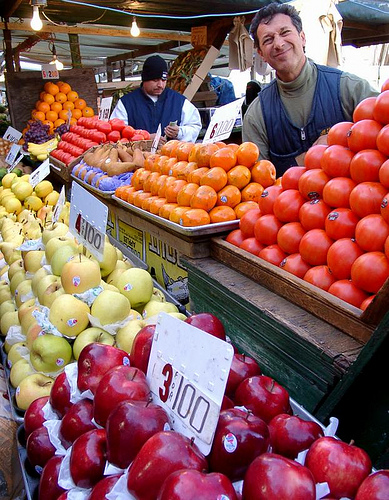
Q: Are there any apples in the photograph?
A: Yes, there are apples.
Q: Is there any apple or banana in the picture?
A: Yes, there are apples.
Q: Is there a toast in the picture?
A: No, there are no toasts.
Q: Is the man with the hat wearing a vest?
A: Yes, the man is wearing a vest.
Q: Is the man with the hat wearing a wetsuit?
A: No, the man is wearing a vest.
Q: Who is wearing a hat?
A: The man is wearing a hat.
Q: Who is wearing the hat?
A: The man is wearing a hat.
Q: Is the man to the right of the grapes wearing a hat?
A: Yes, the man is wearing a hat.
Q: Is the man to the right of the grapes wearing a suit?
A: No, the man is wearing a hat.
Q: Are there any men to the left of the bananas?
A: No, the man is to the right of the bananas.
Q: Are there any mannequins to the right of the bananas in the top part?
A: No, there is a man to the right of the bananas.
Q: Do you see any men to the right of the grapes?
A: Yes, there is a man to the right of the grapes.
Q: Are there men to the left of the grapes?
A: No, the man is to the right of the grapes.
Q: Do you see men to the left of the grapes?
A: No, the man is to the right of the grapes.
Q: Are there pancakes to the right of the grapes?
A: No, there is a man to the right of the grapes.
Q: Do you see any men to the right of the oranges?
A: Yes, there is a man to the right of the oranges.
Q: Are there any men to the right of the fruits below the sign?
A: Yes, there is a man to the right of the oranges.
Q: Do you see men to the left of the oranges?
A: No, the man is to the right of the oranges.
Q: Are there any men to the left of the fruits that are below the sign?
A: No, the man is to the right of the oranges.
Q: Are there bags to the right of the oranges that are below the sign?
A: No, there is a man to the right of the oranges.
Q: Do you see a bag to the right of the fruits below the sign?
A: No, there is a man to the right of the oranges.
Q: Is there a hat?
A: Yes, there is a hat.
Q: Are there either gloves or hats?
A: Yes, there is a hat.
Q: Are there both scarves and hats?
A: No, there is a hat but no scarves.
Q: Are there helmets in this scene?
A: No, there are no helmets.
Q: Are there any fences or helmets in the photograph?
A: No, there are no helmets or fences.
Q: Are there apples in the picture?
A: Yes, there is an apple.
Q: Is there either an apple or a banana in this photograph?
A: Yes, there is an apple.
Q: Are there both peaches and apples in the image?
A: No, there is an apple but no peaches.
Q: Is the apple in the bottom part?
A: Yes, the apple is in the bottom of the image.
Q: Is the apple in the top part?
A: No, the apple is in the bottom of the image.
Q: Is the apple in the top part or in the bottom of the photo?
A: The apple is in the bottom of the image.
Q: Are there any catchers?
A: No, there are no catchers.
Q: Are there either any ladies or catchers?
A: No, there are no catchers or ladies.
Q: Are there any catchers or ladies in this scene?
A: No, there are no catchers or ladies.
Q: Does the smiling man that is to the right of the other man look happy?
A: Yes, the man is happy.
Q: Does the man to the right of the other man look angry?
A: No, the man is happy.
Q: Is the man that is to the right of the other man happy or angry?
A: The man is happy.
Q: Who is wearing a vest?
A: The man is wearing a vest.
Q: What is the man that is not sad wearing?
A: The man is wearing a vest.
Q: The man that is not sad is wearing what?
A: The man is wearing a vest.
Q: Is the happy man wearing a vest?
A: Yes, the man is wearing a vest.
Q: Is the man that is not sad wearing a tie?
A: No, the man is wearing a vest.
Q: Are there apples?
A: Yes, there are apples.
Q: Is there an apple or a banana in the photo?
A: Yes, there are apples.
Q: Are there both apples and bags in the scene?
A: No, there are apples but no bags.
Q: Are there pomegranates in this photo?
A: No, there are no pomegranates.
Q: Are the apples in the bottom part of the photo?
A: Yes, the apples are in the bottom of the image.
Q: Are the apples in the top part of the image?
A: No, the apples are in the bottom of the image.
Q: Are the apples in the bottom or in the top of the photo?
A: The apples are in the bottom of the image.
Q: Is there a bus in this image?
A: No, there are no buses.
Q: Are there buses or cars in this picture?
A: No, there are no buses or cars.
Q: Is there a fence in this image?
A: No, there are no fences.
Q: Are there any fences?
A: No, there are no fences.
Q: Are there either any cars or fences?
A: No, there are no fences or cars.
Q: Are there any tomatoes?
A: Yes, there are tomatoes.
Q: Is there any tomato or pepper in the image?
A: Yes, there are tomatoes.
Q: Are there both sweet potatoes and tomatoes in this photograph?
A: Yes, there are both tomatoes and a sweet potato.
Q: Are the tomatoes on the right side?
A: Yes, the tomatoes are on the right of the image.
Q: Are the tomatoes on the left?
A: No, the tomatoes are on the right of the image.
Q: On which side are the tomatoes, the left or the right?
A: The tomatoes are on the right of the image.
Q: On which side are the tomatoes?
A: The tomatoes are on the right of the image.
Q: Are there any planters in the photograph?
A: No, there are no planters.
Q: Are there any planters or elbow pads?
A: No, there are no planters or elbow pads.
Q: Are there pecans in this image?
A: No, there are no pecans.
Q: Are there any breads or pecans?
A: No, there are no pecans or breads.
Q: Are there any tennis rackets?
A: No, there are no tennis rackets.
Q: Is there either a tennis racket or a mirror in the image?
A: No, there are no rackets or mirrors.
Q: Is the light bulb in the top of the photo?
A: Yes, the light bulb is in the top of the image.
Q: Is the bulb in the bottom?
A: No, the bulb is in the top of the image.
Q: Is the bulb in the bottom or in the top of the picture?
A: The bulb is in the top of the image.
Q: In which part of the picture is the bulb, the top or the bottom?
A: The bulb is in the top of the image.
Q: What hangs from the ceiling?
A: The light bulb hangs from the ceiling.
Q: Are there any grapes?
A: Yes, there are grapes.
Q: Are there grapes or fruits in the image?
A: Yes, there are grapes.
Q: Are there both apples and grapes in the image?
A: Yes, there are both grapes and an apple.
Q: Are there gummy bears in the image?
A: No, there are no gummy bears.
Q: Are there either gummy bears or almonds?
A: No, there are no gummy bears or almonds.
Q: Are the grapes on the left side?
A: Yes, the grapes are on the left of the image.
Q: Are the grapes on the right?
A: No, the grapes are on the left of the image.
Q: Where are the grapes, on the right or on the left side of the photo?
A: The grapes are on the left of the image.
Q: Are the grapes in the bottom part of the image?
A: No, the grapes are in the top of the image.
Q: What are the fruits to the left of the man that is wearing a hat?
A: The fruits are grapes.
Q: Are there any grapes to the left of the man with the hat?
A: Yes, there are grapes to the left of the man.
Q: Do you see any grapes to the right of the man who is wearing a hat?
A: No, the grapes are to the left of the man.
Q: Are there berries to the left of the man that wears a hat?
A: No, there are grapes to the left of the man.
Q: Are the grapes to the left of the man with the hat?
A: Yes, the grapes are to the left of the man.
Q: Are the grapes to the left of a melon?
A: No, the grapes are to the left of the man.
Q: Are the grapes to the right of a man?
A: No, the grapes are to the left of a man.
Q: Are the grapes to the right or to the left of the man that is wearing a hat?
A: The grapes are to the left of the man.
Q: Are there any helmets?
A: No, there are no helmets.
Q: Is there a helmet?
A: No, there are no helmets.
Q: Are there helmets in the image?
A: No, there are no helmets.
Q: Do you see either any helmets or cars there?
A: No, there are no helmets or cars.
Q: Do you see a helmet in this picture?
A: No, there are no helmets.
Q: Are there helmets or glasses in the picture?
A: No, there are no helmets or glasses.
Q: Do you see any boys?
A: No, there are no boys.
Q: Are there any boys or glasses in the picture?
A: No, there are no boys or glasses.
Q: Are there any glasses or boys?
A: No, there are no boys or glasses.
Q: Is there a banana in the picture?
A: Yes, there are bananas.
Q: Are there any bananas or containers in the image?
A: Yes, there are bananas.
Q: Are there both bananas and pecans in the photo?
A: No, there are bananas but no pecans.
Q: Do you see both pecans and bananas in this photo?
A: No, there are bananas but no pecans.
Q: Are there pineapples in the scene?
A: No, there are no pineapples.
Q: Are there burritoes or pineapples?
A: No, there are no pineapples or burritoes.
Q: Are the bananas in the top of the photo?
A: Yes, the bananas are in the top of the image.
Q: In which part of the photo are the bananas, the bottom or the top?
A: The bananas are in the top of the image.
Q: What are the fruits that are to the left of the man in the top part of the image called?
A: The fruits are bananas.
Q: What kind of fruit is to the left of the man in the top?
A: The fruits are bananas.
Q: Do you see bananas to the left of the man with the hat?
A: Yes, there are bananas to the left of the man.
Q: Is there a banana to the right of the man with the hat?
A: No, the bananas are to the left of the man.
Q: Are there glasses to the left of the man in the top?
A: No, there are bananas to the left of the man.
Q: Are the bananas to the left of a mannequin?
A: No, the bananas are to the left of the man.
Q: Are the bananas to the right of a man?
A: No, the bananas are to the left of a man.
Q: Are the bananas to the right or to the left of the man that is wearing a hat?
A: The bananas are to the left of the man.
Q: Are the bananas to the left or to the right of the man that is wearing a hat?
A: The bananas are to the left of the man.